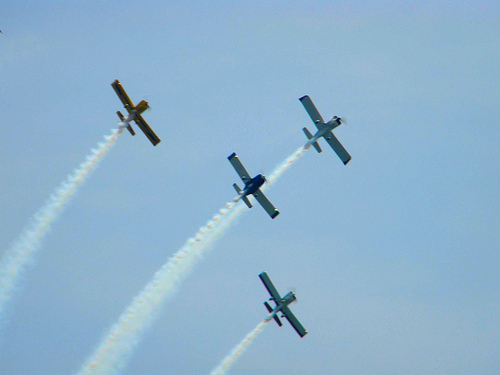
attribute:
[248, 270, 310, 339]
plane — small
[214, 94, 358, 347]
planes — long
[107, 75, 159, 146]
plane — dark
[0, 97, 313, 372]
cloud — white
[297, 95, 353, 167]
leading aircraft — leading 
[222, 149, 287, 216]
airplanes — blue, white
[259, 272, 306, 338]
plane — flying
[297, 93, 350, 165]
jet — white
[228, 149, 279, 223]
jet — white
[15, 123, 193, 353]
smoke — airborne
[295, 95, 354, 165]
chopper — airborne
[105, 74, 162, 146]
chopper — airborne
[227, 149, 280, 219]
chopper — airborne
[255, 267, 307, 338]
chopper — airborne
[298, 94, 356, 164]
planes — flying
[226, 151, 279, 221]
planes — flying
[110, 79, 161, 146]
planes — flying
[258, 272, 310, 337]
planes — flying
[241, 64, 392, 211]
chopper — red tinted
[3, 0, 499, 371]
sky — blue , clear and blue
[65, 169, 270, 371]
cloud — long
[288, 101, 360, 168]
planes — flying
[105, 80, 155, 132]
planes — flying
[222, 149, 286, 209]
planes — flying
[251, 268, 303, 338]
planes — flying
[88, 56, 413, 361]
plane — grouped, flying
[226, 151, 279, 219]
plane — flying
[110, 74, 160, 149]
plane — flying, four, yellow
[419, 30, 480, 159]
sky — clear view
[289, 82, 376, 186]
plane — green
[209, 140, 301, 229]
plane — green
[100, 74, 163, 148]
plane — tiny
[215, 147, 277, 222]
plane — tiny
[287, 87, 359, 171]
plane — tiny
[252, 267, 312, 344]
plane — tiny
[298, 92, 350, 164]
plane — flying